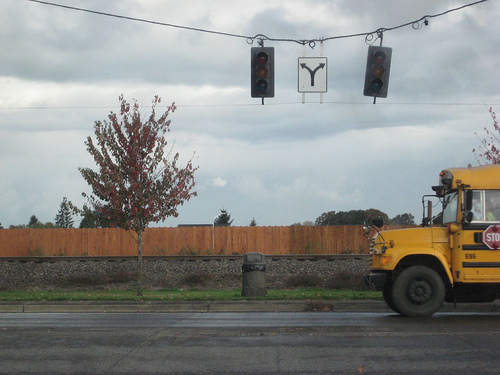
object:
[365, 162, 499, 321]
bus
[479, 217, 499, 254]
sign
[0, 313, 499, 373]
street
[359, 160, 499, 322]
school bus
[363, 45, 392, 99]
traffic light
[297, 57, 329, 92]
sign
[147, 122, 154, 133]
pink leaves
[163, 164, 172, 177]
pink leaves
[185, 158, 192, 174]
pink leaves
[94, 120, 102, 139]
pink leaves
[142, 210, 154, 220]
pink leaves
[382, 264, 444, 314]
tire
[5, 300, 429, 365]
road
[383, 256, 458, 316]
tire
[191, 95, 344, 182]
sky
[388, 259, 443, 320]
wheel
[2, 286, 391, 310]
grass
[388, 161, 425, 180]
ground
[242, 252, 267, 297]
trash can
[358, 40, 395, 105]
traffic light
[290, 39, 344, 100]
sign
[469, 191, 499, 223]
window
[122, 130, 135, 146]
leaves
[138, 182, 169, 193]
leaves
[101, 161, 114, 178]
leaves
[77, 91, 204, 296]
tree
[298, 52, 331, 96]
sign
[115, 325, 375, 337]
dirt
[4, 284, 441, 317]
ground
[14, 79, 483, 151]
clouds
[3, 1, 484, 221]
sky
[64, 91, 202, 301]
maple tree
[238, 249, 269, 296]
trash can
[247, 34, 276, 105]
traffic light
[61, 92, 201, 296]
tree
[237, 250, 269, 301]
trash can